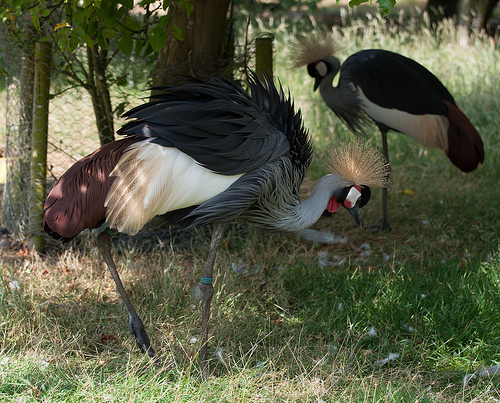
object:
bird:
[41, 59, 394, 376]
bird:
[295, 37, 489, 235]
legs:
[372, 124, 397, 233]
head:
[319, 167, 373, 232]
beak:
[350, 203, 363, 230]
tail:
[40, 131, 153, 241]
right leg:
[192, 208, 225, 382]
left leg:
[92, 215, 152, 367]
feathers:
[96, 137, 245, 240]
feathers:
[117, 74, 313, 175]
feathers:
[306, 243, 401, 267]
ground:
[0, 121, 498, 402]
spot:
[23, 246, 103, 304]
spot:
[89, 324, 124, 350]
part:
[269, 265, 498, 385]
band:
[199, 275, 213, 285]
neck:
[268, 164, 337, 229]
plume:
[324, 140, 393, 191]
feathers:
[419, 114, 448, 152]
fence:
[0, 13, 277, 248]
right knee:
[194, 276, 215, 300]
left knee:
[89, 231, 117, 253]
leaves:
[143, 17, 176, 55]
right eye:
[356, 197, 365, 204]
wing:
[339, 46, 454, 152]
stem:
[28, 40, 57, 253]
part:
[30, 33, 58, 93]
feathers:
[259, 151, 344, 243]